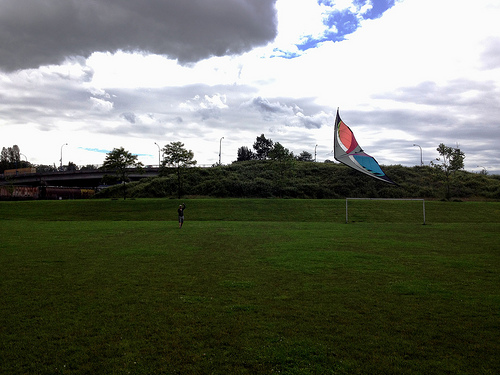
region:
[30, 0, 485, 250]
the sky is cloudy and bright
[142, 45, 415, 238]
the sky is cloudy and bright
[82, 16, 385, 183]
the sky is cloudy and bright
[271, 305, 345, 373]
The grass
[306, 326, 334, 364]
The grass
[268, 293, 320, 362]
The grass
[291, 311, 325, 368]
The grass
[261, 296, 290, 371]
The grass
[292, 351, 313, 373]
The grass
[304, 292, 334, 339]
The grass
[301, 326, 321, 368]
The grass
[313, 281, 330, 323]
The grass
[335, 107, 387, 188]
red white and blue kite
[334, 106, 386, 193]
large red white and blue kite flow by man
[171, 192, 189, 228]
man running in grassy field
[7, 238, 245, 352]
green grass in field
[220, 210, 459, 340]
green grass in field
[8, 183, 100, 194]
train moving under bridge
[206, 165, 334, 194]
green bushes by grassy field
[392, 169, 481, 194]
green bushes by grassy field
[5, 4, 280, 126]
white clouds against blue sky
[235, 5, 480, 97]
white clouds against blue sky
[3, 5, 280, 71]
Cloudy skies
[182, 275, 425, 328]
Lush green grass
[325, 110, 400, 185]
Red, white and blue kite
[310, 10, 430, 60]
Blu skies in the midst of clouds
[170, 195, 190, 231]
Man running with a kite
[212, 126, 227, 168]
Lamp post in the distance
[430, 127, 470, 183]
Tress with clouds in the background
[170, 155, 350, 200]
clusters of high bushes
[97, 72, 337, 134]
gray skies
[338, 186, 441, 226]
soccer net goal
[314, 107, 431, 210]
a kite in the air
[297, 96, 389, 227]
a kite flying in the air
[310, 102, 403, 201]
red blue white kite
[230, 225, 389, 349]
a field of green grass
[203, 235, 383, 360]
a green grass field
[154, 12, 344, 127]
a cloudy blue sky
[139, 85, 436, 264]
a person flying a kite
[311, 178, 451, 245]
a soccor goal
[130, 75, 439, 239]
a person flying the kite low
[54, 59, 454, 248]
a person holding the kite's string